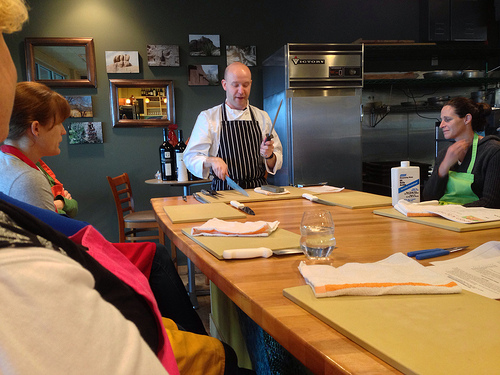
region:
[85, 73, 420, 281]
this is a kitchen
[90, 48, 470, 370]
this is a demonstration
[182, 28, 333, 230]
the man is a chef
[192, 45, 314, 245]
the man is cooking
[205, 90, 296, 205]
the man has an apron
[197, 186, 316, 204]
Long brown cutting board a chef is cutting at.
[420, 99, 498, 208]
A brown haired woman in a green apron.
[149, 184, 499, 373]
A long brown table.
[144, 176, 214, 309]
A tall round metal and wood table.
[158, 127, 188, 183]
Wine bottles on a round table top.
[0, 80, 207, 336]
Red haired woman sitting in a grey shirt.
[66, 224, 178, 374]
Part of a pink apron.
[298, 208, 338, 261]
Two clear glasses of water on the table.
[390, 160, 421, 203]
A large white container with blue and black writing in front of a green apron woman.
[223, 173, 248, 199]
Silver knife in a chefs right hand.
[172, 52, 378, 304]
this is a workshop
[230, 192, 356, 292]
the table is set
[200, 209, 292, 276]
this is a knife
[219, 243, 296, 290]
the handle is white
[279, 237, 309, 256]
the blade is silver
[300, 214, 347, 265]
the glass has water in it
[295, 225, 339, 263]
clear glass filled with water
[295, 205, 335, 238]
clear glass filled with water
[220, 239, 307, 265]
knife with white plastic handle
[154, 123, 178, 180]
dark glass bottle used for wine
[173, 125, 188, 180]
dark glass bottle used for wine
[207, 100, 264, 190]
apron with white and black stripes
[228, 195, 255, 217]
metal knife with white handle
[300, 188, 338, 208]
metal knife with white handle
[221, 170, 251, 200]
metal knife blade with sharp edge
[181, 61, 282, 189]
Bald headed chef with black and white apron on.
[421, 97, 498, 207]
A woman sitting at a table with a green apron.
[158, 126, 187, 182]
Bottles of wine behind a chef.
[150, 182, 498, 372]
A very long brown table.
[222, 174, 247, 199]
A long sharp knife.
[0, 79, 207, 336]
Red headed woman in grey shirt.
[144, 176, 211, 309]
A tall metal and wood round top table.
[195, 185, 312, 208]
Long brown cutting board in front of a chef.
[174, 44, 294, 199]
man holding a knife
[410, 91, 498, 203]
woman in a green apron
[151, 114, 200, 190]
two bottles of wine behind the man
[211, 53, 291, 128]
a view of face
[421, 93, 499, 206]
Woman has green apron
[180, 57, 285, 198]
Chef holding a knife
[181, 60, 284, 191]
Chef is wearing black and white apron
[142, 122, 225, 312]
Wine bottles on the table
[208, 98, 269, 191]
Black and white stripe apron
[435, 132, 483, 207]
Apron is green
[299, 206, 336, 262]
Glass has water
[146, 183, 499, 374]
Glass on the table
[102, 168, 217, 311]
Chair and a table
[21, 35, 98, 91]
Mirror with brown frame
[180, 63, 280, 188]
Man in a striped apron with knives.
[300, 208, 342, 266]
Glass of water on a table.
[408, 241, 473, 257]
Pair of pliers with a blue handle.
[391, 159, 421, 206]
Square white bottle on a table.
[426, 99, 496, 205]
Woman in a black shirt with a green apron.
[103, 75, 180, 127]
Mirror reflecting lights on a wall.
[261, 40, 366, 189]
Large silver appliance with digital red lights.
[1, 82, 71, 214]
woman with red hair in a pony tail.